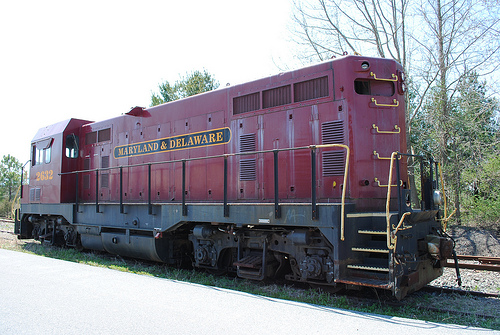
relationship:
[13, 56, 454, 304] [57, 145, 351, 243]
train has rail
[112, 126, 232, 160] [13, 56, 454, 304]
logo on train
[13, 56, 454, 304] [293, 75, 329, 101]
train has window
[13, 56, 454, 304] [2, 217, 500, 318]
train on track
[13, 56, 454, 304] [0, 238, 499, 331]
train by grass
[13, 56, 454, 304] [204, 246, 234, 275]
train has wheel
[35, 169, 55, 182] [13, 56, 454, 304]
logo on train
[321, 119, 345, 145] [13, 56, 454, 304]
vent on train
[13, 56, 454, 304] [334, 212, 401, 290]
train has staircase